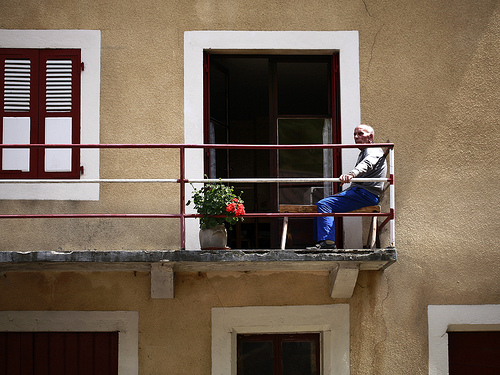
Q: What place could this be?
A: It is a patio.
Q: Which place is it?
A: It is a patio.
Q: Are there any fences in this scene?
A: No, there are no fences.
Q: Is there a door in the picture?
A: Yes, there is a door.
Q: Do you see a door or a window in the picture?
A: Yes, there is a door.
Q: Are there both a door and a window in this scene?
A: Yes, there are both a door and a window.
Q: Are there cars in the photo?
A: No, there are no cars.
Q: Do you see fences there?
A: No, there are no fences.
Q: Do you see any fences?
A: No, there are no fences.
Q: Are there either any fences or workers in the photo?
A: No, there are no fences or workers.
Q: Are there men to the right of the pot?
A: Yes, there is a man to the right of the pot.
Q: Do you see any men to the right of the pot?
A: Yes, there is a man to the right of the pot.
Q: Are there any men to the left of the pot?
A: No, the man is to the right of the pot.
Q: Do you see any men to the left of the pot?
A: No, the man is to the right of the pot.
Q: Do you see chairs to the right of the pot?
A: No, there is a man to the right of the pot.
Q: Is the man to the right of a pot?
A: Yes, the man is to the right of a pot.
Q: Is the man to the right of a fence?
A: No, the man is to the right of a pot.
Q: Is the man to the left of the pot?
A: No, the man is to the right of the pot.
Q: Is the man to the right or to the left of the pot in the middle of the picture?
A: The man is to the right of the pot.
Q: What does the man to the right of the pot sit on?
A: The man sits on the balcony.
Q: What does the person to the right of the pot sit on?
A: The man sits on the balcony.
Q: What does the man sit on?
A: The man sits on the balcony.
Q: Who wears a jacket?
A: The man wears a jacket.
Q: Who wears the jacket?
A: The man wears a jacket.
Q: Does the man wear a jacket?
A: Yes, the man wears a jacket.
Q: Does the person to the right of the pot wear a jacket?
A: Yes, the man wears a jacket.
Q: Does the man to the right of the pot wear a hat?
A: No, the man wears a jacket.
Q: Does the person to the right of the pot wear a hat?
A: No, the man wears a jacket.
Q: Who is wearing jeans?
A: The man is wearing jeans.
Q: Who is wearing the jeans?
A: The man is wearing jeans.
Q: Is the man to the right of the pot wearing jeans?
A: Yes, the man is wearing jeans.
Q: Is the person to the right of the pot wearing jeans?
A: Yes, the man is wearing jeans.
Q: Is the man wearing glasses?
A: No, the man is wearing jeans.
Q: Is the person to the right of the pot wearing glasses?
A: No, the man is wearing jeans.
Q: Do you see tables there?
A: Yes, there is a table.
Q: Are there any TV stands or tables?
A: Yes, there is a table.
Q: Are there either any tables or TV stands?
A: Yes, there is a table.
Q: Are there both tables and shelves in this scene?
A: No, there is a table but no shelves.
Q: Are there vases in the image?
A: No, there are no vases.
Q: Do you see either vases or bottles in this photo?
A: No, there are no vases or bottles.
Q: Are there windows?
A: Yes, there is a window.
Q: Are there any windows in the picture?
A: Yes, there is a window.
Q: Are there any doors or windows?
A: Yes, there is a window.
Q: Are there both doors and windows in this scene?
A: Yes, there are both a window and a door.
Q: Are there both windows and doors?
A: Yes, there are both a window and a door.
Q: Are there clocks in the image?
A: No, there are no clocks.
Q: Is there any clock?
A: No, there are no clocks.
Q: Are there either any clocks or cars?
A: No, there are no clocks or cars.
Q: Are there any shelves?
A: No, there are no shelves.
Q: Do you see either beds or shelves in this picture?
A: No, there are no shelves or beds.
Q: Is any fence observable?
A: No, there are no fences.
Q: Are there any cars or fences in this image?
A: No, there are no fences or cars.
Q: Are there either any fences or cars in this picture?
A: No, there are no fences or cars.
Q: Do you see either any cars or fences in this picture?
A: No, there are no fences or cars.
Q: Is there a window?
A: Yes, there is a window.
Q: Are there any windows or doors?
A: Yes, there is a window.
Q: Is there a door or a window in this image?
A: Yes, there is a window.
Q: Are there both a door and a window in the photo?
A: Yes, there are both a window and a door.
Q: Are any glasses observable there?
A: No, there are no glasses.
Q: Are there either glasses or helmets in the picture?
A: No, there are no glasses or helmets.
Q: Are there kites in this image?
A: No, there are no kites.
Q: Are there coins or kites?
A: No, there are no kites or coins.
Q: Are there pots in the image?
A: Yes, there is a pot.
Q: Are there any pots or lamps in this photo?
A: Yes, there is a pot.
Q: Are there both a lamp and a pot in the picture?
A: No, there is a pot but no lamps.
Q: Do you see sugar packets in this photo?
A: No, there are no sugar packets.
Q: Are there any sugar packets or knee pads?
A: No, there are no sugar packets or knee pads.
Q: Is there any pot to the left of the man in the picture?
A: Yes, there is a pot to the left of the man.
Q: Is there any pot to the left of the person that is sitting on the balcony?
A: Yes, there is a pot to the left of the man.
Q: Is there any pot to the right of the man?
A: No, the pot is to the left of the man.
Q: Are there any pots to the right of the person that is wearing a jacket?
A: No, the pot is to the left of the man.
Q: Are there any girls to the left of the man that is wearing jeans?
A: No, there is a pot to the left of the man.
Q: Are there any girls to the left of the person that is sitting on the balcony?
A: No, there is a pot to the left of the man.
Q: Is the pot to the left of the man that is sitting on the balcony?
A: Yes, the pot is to the left of the man.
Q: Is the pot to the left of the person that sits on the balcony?
A: Yes, the pot is to the left of the man.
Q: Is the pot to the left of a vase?
A: No, the pot is to the left of the man.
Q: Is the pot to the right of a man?
A: No, the pot is to the left of a man.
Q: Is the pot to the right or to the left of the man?
A: The pot is to the left of the man.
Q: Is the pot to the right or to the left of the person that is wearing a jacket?
A: The pot is to the left of the man.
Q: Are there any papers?
A: No, there are no papers.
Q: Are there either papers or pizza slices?
A: No, there are no papers or pizza slices.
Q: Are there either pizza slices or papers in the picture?
A: No, there are no papers or pizza slices.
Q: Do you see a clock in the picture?
A: No, there are no clocks.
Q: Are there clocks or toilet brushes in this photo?
A: No, there are no clocks or toilet brushes.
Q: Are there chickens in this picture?
A: No, there are no chickens.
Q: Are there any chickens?
A: No, there are no chickens.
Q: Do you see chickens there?
A: No, there are no chickens.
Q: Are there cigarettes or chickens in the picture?
A: No, there are no chickens or cigarettes.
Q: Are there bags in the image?
A: No, there are no bags.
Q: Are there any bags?
A: No, there are no bags.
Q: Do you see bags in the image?
A: No, there are no bags.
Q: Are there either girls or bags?
A: No, there are no bags or girls.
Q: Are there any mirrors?
A: No, there are no mirrors.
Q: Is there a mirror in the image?
A: No, there are no mirrors.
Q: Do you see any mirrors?
A: No, there are no mirrors.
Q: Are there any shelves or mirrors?
A: No, there are no mirrors or shelves.